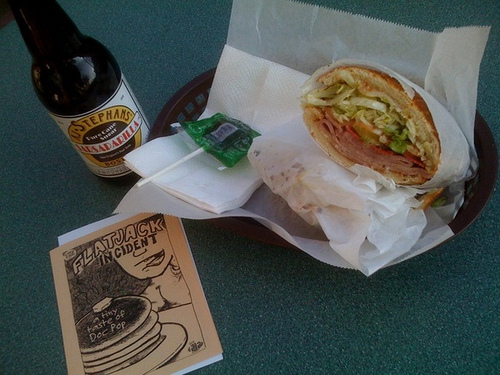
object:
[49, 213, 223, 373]
greeting card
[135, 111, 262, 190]
lollipop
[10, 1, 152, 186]
bottle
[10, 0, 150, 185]
sasparilla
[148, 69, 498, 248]
tray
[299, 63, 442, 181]
food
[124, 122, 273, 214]
napkins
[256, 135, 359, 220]
fries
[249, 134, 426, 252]
paper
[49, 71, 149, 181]
label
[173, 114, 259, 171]
wrapper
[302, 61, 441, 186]
sandwhich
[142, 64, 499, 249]
basket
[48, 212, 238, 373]
book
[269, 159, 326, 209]
grease spots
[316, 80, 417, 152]
lettuce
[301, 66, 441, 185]
bread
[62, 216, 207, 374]
illustration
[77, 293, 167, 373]
pancakes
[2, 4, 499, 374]
table